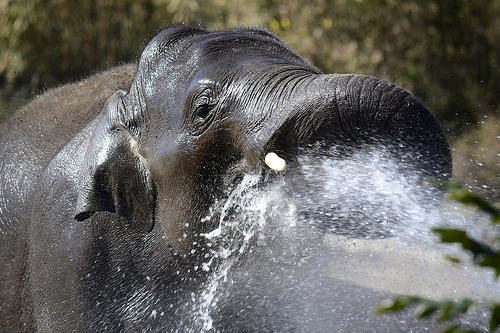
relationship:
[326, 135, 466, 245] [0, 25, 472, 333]
water droplets spraying elephant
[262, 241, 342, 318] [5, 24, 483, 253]
droplets spraying elephant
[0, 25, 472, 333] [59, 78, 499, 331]
elephant drinking water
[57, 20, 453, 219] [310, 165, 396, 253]
head drinking water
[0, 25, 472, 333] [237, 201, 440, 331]
elephant drinking water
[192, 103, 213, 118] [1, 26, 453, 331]
eye on animal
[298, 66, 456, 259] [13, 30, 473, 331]
trunk on elephant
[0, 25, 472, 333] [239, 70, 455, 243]
elephant has trunk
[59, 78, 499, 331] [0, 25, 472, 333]
water under elephant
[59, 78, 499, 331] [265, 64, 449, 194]
water under trunk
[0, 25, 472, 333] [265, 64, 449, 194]
elephant has trunk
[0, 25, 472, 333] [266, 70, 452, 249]
elephant has trunk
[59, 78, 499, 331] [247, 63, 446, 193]
water under trunk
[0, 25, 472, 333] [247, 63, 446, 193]
elephant has trunk